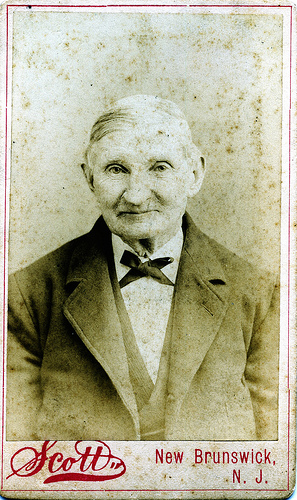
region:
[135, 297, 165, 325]
a white shirt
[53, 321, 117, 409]
man is wearing a suit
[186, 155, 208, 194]
the mans left ear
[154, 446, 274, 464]
red lettering on old photo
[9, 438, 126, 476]
red lettering on old photo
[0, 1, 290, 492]
red boarder on the old photo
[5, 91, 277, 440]
old photo with an even older gentleman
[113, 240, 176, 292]
old man with a bow tie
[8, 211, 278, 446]
old man with three piece suit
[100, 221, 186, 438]
vest on old man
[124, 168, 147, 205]
bent nose on old man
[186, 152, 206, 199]
big ear on old man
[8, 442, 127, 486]
the word Scott on an old photo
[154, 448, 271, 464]
the town new brunswick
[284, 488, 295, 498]
the folded edge of an old photo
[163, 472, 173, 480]
a couple of rusted specks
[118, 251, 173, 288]
an x shaped bow tie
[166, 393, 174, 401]
a cloth covered button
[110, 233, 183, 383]
a white shirt on an old man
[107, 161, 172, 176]
kindly eyes on an elderly man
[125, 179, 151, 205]
a bulbous nose on a man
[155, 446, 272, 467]
red lettering on the old photo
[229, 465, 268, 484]
red lettering on the old photo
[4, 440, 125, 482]
red lettering on the old photo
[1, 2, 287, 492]
red border on the old photo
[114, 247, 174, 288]
bow tie on old man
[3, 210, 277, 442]
three piece suit on old man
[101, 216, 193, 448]
vest on old man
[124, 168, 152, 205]
bent nose on old man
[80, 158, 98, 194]
big ear on old man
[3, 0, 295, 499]
An old portrait of a man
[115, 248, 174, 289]
Black bow tie on a man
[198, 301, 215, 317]
Buttonhole in a lapel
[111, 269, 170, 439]
Vest underneath a coat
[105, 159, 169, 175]
Eyes in man's face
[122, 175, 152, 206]
Nose on man's face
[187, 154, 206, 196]
Ear on a man's head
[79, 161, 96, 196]
Ear on a man's head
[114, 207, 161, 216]
Mouth on a man's face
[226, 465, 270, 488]
N.J. is written on the photo.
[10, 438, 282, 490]
Red writing is on the photo.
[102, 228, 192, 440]
pin-striped vest under the coat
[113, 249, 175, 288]
dark bowtie made of ribbon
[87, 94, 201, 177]
hair parted on the side and combed over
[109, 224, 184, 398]
white shirt under the vest and coat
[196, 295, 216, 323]
button hole on the lapel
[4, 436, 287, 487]
red lettering on the border around the photo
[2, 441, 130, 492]
the word scott on sign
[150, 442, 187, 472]
the word new on sign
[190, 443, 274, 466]
the word Brunswick on sign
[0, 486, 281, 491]
a red line on sign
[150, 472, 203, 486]
rust spots on the sign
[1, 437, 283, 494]
words written in red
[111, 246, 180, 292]
a black bow tie on man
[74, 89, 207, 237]
the face of a old man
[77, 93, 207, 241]
the man has grey hair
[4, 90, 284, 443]
the man is wearing a suit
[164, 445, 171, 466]
A letter on a sign.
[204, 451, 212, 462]
A letter on a sign.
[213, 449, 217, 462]
A letter on a sign.